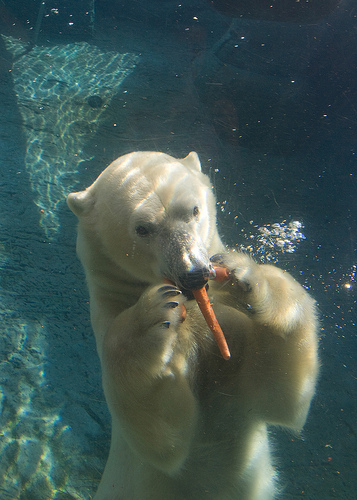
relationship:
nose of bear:
[180, 262, 212, 290] [54, 143, 345, 497]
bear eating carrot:
[66, 151, 322, 499] [183, 284, 237, 358]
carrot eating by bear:
[183, 284, 237, 358] [66, 151, 322, 499]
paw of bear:
[124, 270, 191, 355] [54, 143, 345, 497]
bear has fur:
[66, 151, 322, 499] [113, 155, 152, 217]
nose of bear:
[170, 257, 216, 292] [66, 151, 322, 499]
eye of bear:
[193, 205, 197, 215] [66, 151, 322, 499]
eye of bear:
[135, 224, 149, 234] [66, 151, 322, 499]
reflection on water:
[5, 40, 140, 251] [0, 0, 355, 498]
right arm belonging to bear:
[96, 281, 199, 476] [88, 152, 328, 459]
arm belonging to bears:
[221, 256, 317, 434] [64, 150, 316, 497]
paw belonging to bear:
[124, 270, 190, 381] [66, 151, 322, 499]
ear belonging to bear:
[53, 170, 102, 240] [47, 115, 351, 491]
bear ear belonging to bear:
[61, 186, 93, 217] [51, 133, 322, 443]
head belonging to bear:
[47, 128, 261, 328] [66, 151, 322, 499]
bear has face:
[66, 151, 322, 499] [76, 156, 234, 293]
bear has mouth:
[54, 143, 345, 497] [178, 270, 220, 293]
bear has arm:
[54, 143, 345, 497] [97, 276, 189, 373]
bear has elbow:
[66, 151, 322, 499] [263, 370, 313, 435]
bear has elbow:
[66, 151, 322, 499] [133, 424, 193, 477]